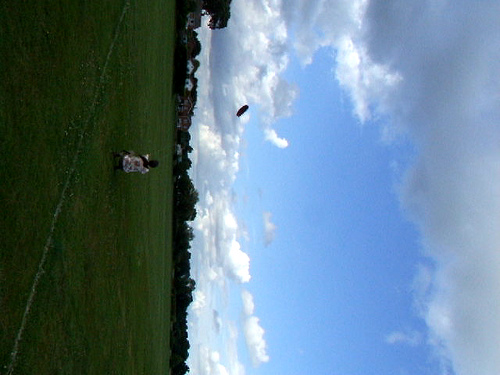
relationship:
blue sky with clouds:
[291, 185, 373, 264] [401, 52, 498, 253]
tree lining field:
[178, 0, 230, 32] [2, 2, 192, 369]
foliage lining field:
[170, 42, 206, 374] [2, 2, 192, 369]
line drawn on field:
[51, 67, 158, 161] [2, 2, 192, 369]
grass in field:
[1, 56, 161, 371] [2, 2, 192, 369]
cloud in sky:
[216, 234, 252, 283] [314, 272, 378, 336]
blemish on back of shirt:
[131, 155, 146, 170] [124, 152, 144, 179]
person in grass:
[116, 150, 161, 174] [0, 0, 179, 374]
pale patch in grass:
[113, 283, 133, 329] [82, 273, 163, 354]